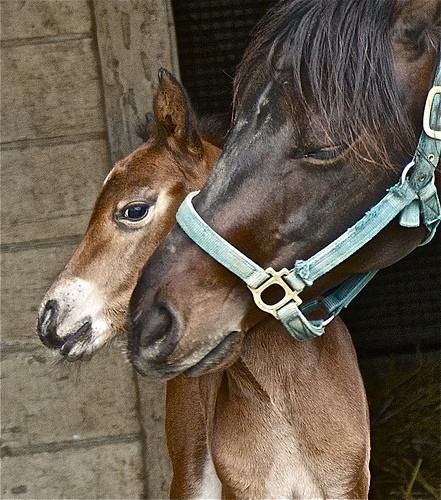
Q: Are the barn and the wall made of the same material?
A: Yes, both the barn and the wall are made of wood.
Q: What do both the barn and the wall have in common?
A: The material, both the barn and the wall are wooden.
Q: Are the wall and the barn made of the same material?
A: Yes, both the wall and the barn are made of wood.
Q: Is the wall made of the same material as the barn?
A: Yes, both the wall and the barn are made of wood.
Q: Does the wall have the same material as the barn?
A: Yes, both the wall and the barn are made of wood.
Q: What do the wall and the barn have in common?
A: The material, both the wall and the barn are wooden.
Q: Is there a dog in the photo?
A: No, there are no dogs.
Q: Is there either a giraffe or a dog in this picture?
A: No, there are no dogs or giraffes.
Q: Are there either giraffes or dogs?
A: No, there are no dogs or giraffes.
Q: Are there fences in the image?
A: No, there are no fences.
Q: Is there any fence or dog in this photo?
A: No, there are no fences or dogs.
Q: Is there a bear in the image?
A: No, there are no bears.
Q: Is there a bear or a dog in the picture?
A: No, there are no bears or dogs.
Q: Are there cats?
A: No, there are no cats.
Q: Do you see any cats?
A: No, there are no cats.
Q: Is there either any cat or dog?
A: No, there are no cats or dogs.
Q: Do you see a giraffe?
A: No, there are no giraffes.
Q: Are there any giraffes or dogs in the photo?
A: No, there are no giraffes or dogs.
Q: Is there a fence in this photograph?
A: No, there are no fences.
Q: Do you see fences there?
A: No, there are no fences.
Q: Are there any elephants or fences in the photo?
A: No, there are no fences or elephants.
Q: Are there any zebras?
A: No, there are no zebras.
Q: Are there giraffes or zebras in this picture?
A: No, there are no zebras or giraffes.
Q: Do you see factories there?
A: No, there are no factories.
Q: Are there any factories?
A: No, there are no factories.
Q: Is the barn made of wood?
A: Yes, the barn is made of wood.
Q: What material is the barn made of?
A: The barn is made of wood.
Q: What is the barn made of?
A: The barn is made of wood.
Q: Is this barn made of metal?
A: No, the barn is made of wood.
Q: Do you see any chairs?
A: No, there are no chairs.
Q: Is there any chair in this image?
A: No, there are no chairs.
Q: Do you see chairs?
A: No, there are no chairs.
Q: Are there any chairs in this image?
A: No, there are no chairs.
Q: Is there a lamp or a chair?
A: No, there are no chairs or lamps.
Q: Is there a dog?
A: No, there are no dogs.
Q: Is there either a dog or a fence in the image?
A: No, there are no dogs or fences.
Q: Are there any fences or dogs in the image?
A: No, there are no dogs or fences.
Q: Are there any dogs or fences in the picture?
A: No, there are no dogs or fences.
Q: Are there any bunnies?
A: No, there are no bunnies.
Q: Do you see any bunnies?
A: No, there are no bunnies.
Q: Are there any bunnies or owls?
A: No, there are no bunnies or owls.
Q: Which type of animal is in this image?
A: The animal is a calf.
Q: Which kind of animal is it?
A: The animal is a calf.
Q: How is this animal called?
A: This is a calf.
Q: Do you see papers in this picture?
A: No, there are no papers.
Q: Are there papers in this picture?
A: No, there are no papers.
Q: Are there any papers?
A: No, there are no papers.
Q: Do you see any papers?
A: No, there are no papers.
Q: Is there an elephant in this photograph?
A: No, there are no elephants.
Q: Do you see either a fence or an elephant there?
A: No, there are no elephants or fences.